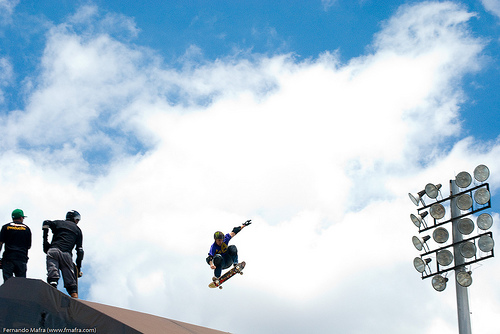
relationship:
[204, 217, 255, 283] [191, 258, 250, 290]
man with a skateboard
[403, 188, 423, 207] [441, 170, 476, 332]
light with a pole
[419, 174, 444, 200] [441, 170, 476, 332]
light with a pole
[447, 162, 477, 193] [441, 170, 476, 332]
light with a pole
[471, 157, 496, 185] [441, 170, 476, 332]
light with a pole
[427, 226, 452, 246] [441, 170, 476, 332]
light with a pole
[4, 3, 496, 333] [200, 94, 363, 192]
sky with clouds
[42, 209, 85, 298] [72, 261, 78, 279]
man with skateboard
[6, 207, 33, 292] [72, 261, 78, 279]
person with skateboard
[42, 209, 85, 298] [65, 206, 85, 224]
man wearing helmet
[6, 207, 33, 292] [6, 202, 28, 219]
person wearing hat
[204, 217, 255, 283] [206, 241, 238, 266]
man wearing t-shirt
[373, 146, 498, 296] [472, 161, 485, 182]
light stand with bulb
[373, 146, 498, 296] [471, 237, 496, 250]
light stand with bulb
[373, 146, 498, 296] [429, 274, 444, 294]
light stand with bulb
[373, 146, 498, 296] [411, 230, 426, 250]
light stand with bulb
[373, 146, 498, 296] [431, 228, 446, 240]
light stand with bulb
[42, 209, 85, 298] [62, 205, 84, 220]
man wears helmet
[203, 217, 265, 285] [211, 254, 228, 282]
man holds h leg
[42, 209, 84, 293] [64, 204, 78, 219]
man wears helmet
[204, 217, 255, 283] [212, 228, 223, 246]
man wears helmet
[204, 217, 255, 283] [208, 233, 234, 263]
man has t-shirt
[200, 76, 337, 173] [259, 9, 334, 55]
clouds in sky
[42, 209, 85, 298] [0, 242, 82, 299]
man wearing pants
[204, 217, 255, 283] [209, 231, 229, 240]
man wearing helmet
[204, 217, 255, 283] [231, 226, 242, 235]
man wearing elbow pad